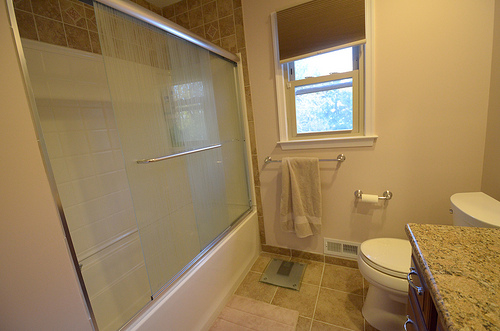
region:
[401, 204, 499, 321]
Granite countertop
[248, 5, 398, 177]
Window on the wall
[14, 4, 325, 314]
Separate shower area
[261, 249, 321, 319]
Weighing scale in the bathroom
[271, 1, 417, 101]
Brown shade on the window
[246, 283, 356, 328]
Light brown tiles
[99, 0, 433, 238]
Brushed nickel bathroom hardware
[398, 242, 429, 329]
Wooden cabinets with drawers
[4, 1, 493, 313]
Neutral color scheme in the bathroom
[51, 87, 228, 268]
White tiles in the shower area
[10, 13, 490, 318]
bathroom in white, tan and brown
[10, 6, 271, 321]
glass doors over bathtub edge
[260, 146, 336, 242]
towel folded over rod under window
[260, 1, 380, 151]
window overlooking trees partially covered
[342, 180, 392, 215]
toilet paper holder attached to wall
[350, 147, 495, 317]
white toilet set into corner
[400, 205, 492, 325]
stone vanity top and cabinets next to toilet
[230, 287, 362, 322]
square brown tiles under bathmat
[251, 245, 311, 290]
metal panel set into floor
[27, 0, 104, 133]
panel of brown tiles over white tiles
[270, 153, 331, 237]
a towel on a rack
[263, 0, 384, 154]
a window in a bathroom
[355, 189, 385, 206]
a toilet paper roll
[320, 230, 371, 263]
a white vent in a wall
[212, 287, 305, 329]
a rug outside of a shower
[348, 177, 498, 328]
a white toilet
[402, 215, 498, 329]
a marble style bathroom counter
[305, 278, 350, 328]
a brown tile floor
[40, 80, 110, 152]
a white tile wall in a shower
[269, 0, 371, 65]
pulled up blinds in a window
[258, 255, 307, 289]
clear scale with digital readout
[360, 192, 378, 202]
partially used roll of toilet paper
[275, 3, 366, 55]
tan window shade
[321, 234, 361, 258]
white wall vent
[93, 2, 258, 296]
clear shower door panel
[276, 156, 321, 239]
towel folded over towel rack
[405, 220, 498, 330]
brown granite counter top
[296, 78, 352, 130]
window pane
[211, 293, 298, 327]
cream colored bath mat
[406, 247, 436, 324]
dark brown wooden drawer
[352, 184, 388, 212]
A roll of toilet paper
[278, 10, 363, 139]
A bathroom window is in view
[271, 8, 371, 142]
Photo was taken in the daytime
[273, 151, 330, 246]
A bathroom towel is hanging up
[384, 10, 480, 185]
The wall is white in color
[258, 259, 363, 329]
The bathroom floor is made out of tiles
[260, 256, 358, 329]
The tiles are light brown in color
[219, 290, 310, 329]
A light pink bathroom rug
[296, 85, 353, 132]
Trees are outside the window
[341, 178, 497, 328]
The toilet seat is down